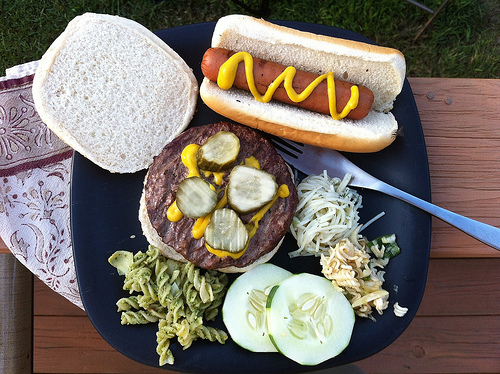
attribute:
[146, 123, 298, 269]
hamburger — brown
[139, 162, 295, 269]
bun — white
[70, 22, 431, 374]
plate — blue, square, black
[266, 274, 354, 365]
cucumber — green, sliced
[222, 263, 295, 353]
cucumber — green, sliced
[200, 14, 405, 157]
bun — white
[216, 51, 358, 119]
mustard — yellow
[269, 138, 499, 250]
fork — steel, silver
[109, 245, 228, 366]
pasta salad — light green, small amount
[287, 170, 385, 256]
noodles — plain, white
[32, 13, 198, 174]
bun — white, empty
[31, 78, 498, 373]
table — wooden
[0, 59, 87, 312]
napkin — patterned